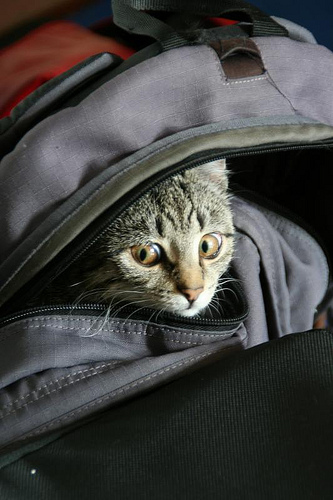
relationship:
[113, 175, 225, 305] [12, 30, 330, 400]
cat in a backpack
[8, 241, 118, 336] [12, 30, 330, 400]
zipper on a backpack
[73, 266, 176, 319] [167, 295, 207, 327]
whiskers on a cat mouth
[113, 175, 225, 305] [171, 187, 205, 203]
cat has gray fur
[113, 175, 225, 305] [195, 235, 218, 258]
cat has green eyes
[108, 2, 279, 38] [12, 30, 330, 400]
strap on backpack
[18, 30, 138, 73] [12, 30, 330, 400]
patch on backpack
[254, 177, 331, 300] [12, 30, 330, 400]
lining in backpack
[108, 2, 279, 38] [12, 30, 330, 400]
handle of backpack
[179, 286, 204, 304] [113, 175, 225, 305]
nose of kitten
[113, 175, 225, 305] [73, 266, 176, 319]
kitten has whiskers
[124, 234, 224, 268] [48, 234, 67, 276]
eyes looking to right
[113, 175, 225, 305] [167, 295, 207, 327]
kitten has a tiny mouth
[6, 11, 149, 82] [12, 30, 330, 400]
red bag behind backpack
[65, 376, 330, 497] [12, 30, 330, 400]
black bag in front of backpack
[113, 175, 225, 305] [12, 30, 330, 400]
cat inside of a backpack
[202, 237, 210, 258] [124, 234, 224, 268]
pupil in cat eyes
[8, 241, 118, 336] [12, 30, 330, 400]
zipper on backpack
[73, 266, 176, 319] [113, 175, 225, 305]
whiskers on cat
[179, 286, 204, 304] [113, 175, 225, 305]
nose on cat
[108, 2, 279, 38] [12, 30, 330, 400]
handle on backpack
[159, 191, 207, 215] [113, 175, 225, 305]
stripes on cat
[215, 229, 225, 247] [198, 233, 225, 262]
whites of cat eye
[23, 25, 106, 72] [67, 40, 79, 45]
reflection on plastic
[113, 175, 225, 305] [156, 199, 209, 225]
cat peeking its head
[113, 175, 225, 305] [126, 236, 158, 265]
cat left eye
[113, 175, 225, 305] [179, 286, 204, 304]
cat has a nose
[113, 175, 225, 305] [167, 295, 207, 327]
cat has a mouth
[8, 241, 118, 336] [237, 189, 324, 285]
zipper on jacket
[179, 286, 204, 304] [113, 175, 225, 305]
nose on a cat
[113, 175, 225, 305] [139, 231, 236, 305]
cat showing face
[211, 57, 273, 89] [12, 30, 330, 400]
stitching on backpack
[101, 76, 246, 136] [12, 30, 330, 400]
material of backpack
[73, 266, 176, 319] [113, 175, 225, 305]
whiskers of a cat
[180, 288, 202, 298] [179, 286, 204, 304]
pink butterly shaped nose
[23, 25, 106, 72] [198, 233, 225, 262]
reflection in eye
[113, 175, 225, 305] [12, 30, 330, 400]
cat peeking out of backpack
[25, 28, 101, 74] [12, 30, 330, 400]
red behind backpack